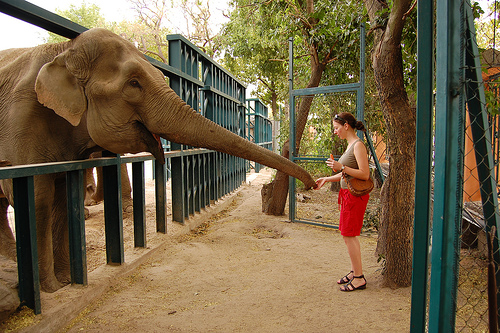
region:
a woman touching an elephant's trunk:
[310, 105, 382, 297]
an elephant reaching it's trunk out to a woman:
[1, 20, 321, 299]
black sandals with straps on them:
[336, 267, 370, 295]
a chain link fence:
[431, 1, 498, 331]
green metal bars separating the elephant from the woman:
[1, 0, 276, 320]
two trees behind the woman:
[207, 0, 427, 290]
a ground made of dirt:
[70, 183, 420, 332]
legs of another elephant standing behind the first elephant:
[75, 158, 143, 221]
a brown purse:
[335, 163, 379, 197]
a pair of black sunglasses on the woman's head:
[329, 113, 349, 125]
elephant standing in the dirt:
[0, 27, 318, 314]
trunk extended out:
[126, 73, 317, 202]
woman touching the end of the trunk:
[289, 109, 393, 297]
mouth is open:
[130, 118, 182, 169]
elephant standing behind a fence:
[1, 29, 315, 311]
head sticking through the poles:
[35, 13, 192, 207]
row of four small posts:
[14, 166, 154, 308]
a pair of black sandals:
[334, 268, 371, 295]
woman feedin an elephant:
[4, 18, 386, 314]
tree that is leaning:
[208, 1, 368, 223]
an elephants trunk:
[159, 97, 320, 194]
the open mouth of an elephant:
[138, 118, 179, 159]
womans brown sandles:
[336, 269, 368, 291]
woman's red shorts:
[336, 188, 370, 236]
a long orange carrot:
[327, 152, 337, 172]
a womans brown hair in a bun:
[333, 113, 368, 135]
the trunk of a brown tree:
[373, 110, 421, 293]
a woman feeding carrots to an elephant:
[3, 24, 374, 292]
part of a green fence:
[415, 0, 499, 332]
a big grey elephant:
[0, 30, 324, 291]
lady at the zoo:
[315, 102, 382, 312]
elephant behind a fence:
[5, 24, 207, 286]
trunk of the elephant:
[188, 110, 320, 194]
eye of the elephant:
[125, 73, 150, 107]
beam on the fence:
[63, 177, 91, 289]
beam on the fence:
[10, 178, 45, 314]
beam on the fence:
[127, 165, 162, 253]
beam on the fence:
[171, 165, 184, 223]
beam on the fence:
[194, 164, 207, 213]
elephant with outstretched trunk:
[1, 17, 319, 304]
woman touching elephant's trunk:
[291, 106, 385, 293]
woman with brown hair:
[309, 107, 375, 294]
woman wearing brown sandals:
[313, 108, 375, 292]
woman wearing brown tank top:
[313, 107, 377, 294]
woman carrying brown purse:
[314, 108, 374, 293]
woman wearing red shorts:
[310, 110, 376, 293]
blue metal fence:
[3, 0, 277, 313]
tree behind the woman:
[336, 2, 431, 287]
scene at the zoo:
[0, 0, 499, 331]